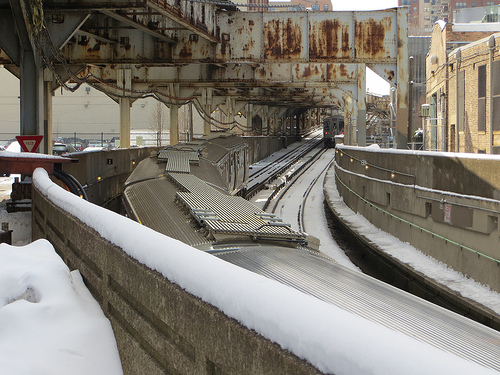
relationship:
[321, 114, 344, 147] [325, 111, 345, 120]
train has top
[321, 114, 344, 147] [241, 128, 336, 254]
train on tracks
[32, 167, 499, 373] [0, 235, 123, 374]
wall covered in snow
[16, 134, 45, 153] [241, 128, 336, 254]
sign near tracks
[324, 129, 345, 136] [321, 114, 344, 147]
lights are on train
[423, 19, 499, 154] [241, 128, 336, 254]
building surrounding tracks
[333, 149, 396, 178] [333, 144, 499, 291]
lights on wall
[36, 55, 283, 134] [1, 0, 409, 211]
wires are on overpass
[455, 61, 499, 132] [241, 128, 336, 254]
windows next to tracks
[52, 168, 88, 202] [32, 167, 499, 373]
cables going over wall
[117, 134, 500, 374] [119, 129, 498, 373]
train has top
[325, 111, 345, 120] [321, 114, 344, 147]
top on train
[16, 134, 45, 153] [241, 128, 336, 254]
sign next to tracks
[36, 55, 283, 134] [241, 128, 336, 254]
wires hang by tracks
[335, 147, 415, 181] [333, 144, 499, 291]
hand rail on wall